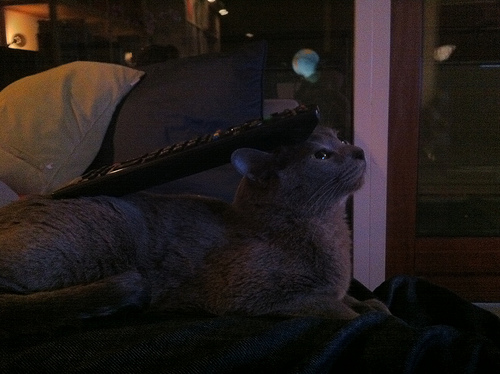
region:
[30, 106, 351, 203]
A long black remote controller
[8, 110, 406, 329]
The cat is grey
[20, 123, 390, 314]
Cat is lying down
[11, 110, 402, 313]
Cat is on top of a blanket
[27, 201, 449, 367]
Blanket is dark blue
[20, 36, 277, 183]
Pillows are beige and dark blue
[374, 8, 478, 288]
Door has a glass window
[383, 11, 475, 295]
The door is brown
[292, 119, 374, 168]
Cat has yellow eyes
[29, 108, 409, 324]
The remote control is on top of the cat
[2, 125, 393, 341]
cat laying down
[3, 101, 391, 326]
cat with a remote leaning on its head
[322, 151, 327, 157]
light shining in the cat's eye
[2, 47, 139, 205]
tan pillow that is propped up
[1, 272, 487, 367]
dark fuzzy blanket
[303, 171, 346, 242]
cluster of long white whiskers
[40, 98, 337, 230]
black remote that is propped up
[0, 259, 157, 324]
tail curled around body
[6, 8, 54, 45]
light in the distance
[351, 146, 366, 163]
small black nose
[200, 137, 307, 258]
a cat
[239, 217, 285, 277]
a cat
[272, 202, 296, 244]
a cat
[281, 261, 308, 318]
a cat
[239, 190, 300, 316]
a cat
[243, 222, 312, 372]
a cat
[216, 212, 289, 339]
a cat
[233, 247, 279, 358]
a cat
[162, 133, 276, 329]
a cat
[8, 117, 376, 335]
a grey cat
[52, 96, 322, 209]
a television remote on a cat's head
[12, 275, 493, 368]
blue jean pants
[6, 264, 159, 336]
the gray tail of a cat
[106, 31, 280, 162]
a dark blue pillow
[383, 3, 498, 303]
a brown wood door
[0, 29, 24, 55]
a light shining in the background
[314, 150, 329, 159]
a dark cat eye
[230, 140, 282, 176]
a cat ear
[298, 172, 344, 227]
white cat whiskers on a gray cat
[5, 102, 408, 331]
cat with a remote control on its head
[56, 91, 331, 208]
black remote propped up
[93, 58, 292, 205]
navy blue pillow propped up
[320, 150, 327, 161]
light shining in the small black eye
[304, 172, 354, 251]
long, white whiskers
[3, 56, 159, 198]
tan pillow laying on the blue one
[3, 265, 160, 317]
long tail wrapped around the body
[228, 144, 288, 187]
tiny ear